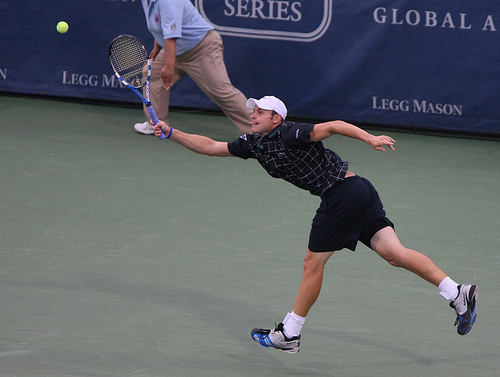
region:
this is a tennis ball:
[55, 19, 70, 34]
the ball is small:
[52, 19, 72, 36]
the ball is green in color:
[54, 20, 68, 36]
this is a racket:
[102, 32, 178, 139]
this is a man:
[106, 31, 476, 349]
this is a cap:
[246, 97, 287, 113]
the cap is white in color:
[264, 97, 285, 107]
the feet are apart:
[259, 220, 476, 374]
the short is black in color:
[316, 194, 365, 232]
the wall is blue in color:
[319, 44, 392, 80]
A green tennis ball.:
[53, 21, 71, 33]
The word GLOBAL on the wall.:
[370, 5, 470, 32]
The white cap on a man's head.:
[242, 93, 288, 122]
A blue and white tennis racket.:
[107, 32, 166, 137]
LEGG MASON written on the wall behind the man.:
[369, 94, 464, 120]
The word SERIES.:
[221, 0, 306, 22]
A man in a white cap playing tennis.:
[148, 96, 479, 353]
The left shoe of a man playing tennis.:
[249, 324, 301, 354]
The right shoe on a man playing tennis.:
[450, 277, 479, 337]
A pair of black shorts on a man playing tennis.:
[302, 174, 394, 253]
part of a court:
[89, 186, 137, 241]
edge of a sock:
[289, 307, 309, 324]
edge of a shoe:
[253, 335, 270, 347]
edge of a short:
[317, 228, 359, 262]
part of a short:
[331, 189, 386, 234]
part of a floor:
[181, 307, 214, 335]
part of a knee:
[298, 252, 316, 269]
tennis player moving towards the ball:
[95, 21, 478, 353]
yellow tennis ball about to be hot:
[55, 18, 72, 39]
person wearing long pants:
[116, 1, 273, 148]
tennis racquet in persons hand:
[103, 31, 175, 141]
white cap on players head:
[246, 88, 292, 121]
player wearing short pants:
[300, 171, 435, 261]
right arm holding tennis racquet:
[143, 112, 245, 164]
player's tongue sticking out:
[248, 116, 260, 128]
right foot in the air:
[420, 263, 483, 334]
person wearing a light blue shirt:
[130, 1, 216, 49]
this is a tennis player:
[160, 85, 475, 356]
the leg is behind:
[370, 240, 463, 335]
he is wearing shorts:
[318, 178, 378, 238]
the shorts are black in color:
[324, 185, 374, 237]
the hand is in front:
[146, 117, 232, 157]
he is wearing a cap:
[249, 92, 281, 112]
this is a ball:
[55, 12, 76, 36]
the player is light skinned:
[382, 234, 396, 251]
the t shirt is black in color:
[270, 127, 310, 182]